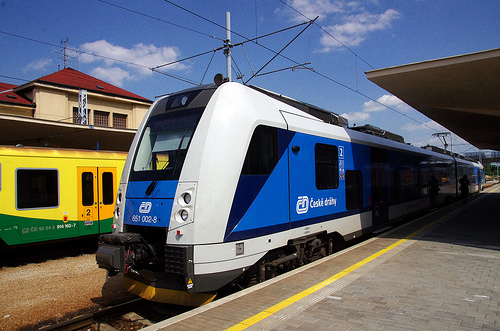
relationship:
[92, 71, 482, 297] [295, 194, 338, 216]
train has name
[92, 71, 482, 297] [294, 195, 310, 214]
train has logo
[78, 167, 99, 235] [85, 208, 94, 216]
door has number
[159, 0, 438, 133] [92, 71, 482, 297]
wire for train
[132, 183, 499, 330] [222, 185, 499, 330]
platform has line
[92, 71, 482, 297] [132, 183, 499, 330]
train boarding platform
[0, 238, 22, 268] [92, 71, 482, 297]
wheels on train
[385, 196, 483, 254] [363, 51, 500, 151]
shadow cast by overhang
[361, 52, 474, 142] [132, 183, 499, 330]
overhang for platform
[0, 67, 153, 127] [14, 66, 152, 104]
building has roof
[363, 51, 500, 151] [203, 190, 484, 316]
overhang over platform